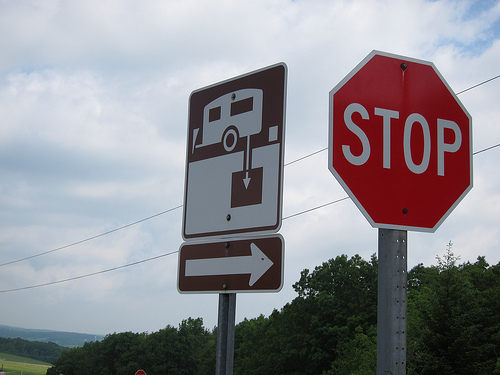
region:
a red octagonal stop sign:
[323, 44, 477, 236]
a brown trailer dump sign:
[176, 58, 287, 296]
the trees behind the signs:
[43, 246, 497, 373]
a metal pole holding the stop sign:
[368, 211, 407, 373]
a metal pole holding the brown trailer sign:
[206, 271, 241, 371]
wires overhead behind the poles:
[0, 193, 190, 291]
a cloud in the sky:
[6, 67, 179, 225]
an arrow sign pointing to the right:
[170, 230, 290, 298]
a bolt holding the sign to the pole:
[389, 53, 415, 78]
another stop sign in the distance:
[128, 360, 150, 373]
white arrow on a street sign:
[197, 248, 266, 280]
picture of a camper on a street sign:
[201, 107, 268, 147]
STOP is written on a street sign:
[359, 110, 446, 176]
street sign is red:
[355, 62, 455, 212]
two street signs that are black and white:
[178, 80, 269, 302]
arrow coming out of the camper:
[245, 122, 256, 176]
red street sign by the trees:
[130, 372, 147, 373]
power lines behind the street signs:
[292, 152, 349, 214]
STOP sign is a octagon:
[369, 64, 433, 229]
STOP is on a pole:
[375, 211, 416, 322]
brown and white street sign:
[176, 60, 284, 236]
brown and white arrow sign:
[178, 238, 283, 294]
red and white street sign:
[325, 48, 474, 234]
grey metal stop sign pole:
[376, 228, 408, 374]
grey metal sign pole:
[216, 295, 236, 374]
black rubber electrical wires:
[3, 76, 498, 298]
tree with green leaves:
[297, 253, 381, 374]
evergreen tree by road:
[420, 243, 469, 373]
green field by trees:
[1, 355, 54, 373]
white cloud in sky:
[3, 64, 175, 171]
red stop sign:
[321, 44, 481, 374]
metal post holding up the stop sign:
[369, 217, 414, 374]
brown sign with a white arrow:
[166, 231, 288, 301]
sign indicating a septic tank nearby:
[176, 56, 290, 248]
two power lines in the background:
[1, 63, 498, 301]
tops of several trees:
[41, 238, 497, 374]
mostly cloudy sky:
[1, 0, 496, 355]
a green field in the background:
[0, 350, 57, 373]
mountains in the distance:
[0, 323, 110, 353]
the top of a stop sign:
[130, 365, 151, 373]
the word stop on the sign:
[347, 101, 459, 178]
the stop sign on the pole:
[331, 52, 473, 237]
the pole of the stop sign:
[371, 231, 416, 374]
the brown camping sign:
[188, 88, 286, 292]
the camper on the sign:
[195, 81, 280, 176]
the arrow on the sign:
[184, 246, 276, 291]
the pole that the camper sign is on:
[215, 295, 241, 372]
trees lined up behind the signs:
[50, 260, 482, 367]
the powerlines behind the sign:
[2, 79, 492, 299]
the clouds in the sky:
[20, 21, 476, 255]